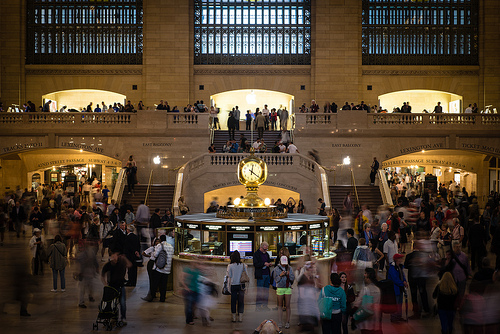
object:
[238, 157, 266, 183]
clock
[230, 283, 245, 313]
pants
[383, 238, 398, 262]
shirt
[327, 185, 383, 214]
staircase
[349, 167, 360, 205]
rail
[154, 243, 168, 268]
backpack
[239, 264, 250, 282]
bag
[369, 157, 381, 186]
person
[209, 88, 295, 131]
hallway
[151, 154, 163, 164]
light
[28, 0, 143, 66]
window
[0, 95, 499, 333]
people